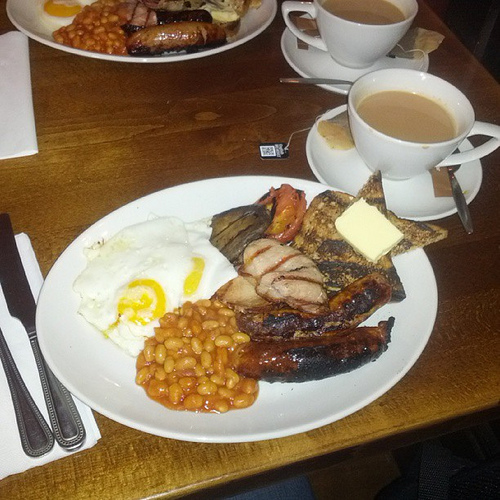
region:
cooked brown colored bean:
[231, 327, 248, 343]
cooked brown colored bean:
[241, 376, 256, 396]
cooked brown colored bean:
[233, 391, 257, 407]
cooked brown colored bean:
[213, 395, 228, 414]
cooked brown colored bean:
[179, 389, 204, 409]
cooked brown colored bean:
[167, 381, 182, 404]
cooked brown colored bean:
[133, 362, 149, 384]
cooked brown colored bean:
[176, 354, 196, 371]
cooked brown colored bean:
[196, 378, 219, 395]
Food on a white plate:
[34, 171, 439, 445]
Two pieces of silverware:
[0, 210, 85, 459]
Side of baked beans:
[131, 295, 258, 413]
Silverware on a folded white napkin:
[0, 212, 101, 488]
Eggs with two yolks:
[72, 214, 235, 357]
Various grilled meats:
[210, 170, 447, 382]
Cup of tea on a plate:
[306, 67, 483, 220]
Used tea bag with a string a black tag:
[256, 107, 355, 162]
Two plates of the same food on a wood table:
[0, 0, 499, 499]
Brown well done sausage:
[237, 315, 394, 385]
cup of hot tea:
[288, 59, 487, 221]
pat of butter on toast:
[315, 193, 410, 264]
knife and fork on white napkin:
[1, 185, 93, 455]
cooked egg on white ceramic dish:
[59, 213, 216, 333]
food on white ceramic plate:
[30, 168, 442, 446]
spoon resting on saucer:
[421, 133, 486, 243]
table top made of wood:
[51, 98, 197, 170]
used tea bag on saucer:
[307, 105, 367, 147]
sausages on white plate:
[243, 270, 407, 363]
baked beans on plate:
[136, 296, 256, 413]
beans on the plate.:
[180, 345, 210, 378]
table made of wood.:
[432, 370, 465, 408]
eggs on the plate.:
[117, 252, 172, 305]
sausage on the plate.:
[289, 337, 363, 365]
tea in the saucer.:
[397, 106, 431, 126]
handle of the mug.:
[486, 123, 492, 152]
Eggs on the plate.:
[71, 207, 238, 352]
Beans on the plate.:
[126, 296, 262, 412]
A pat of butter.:
[332, 195, 405, 265]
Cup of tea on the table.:
[345, 66, 497, 182]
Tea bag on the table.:
[247, 104, 357, 162]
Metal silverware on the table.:
[2, 204, 91, 460]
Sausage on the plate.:
[122, 15, 230, 55]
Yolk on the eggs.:
[115, 250, 209, 327]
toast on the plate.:
[295, 170, 445, 305]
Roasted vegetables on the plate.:
[210, 183, 310, 266]